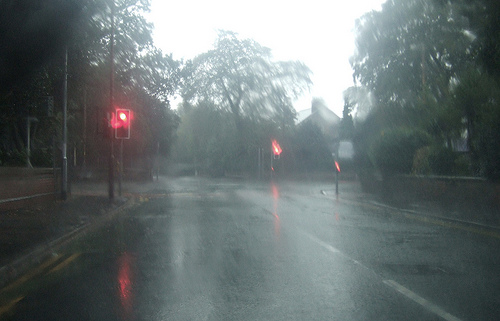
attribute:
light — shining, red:
[113, 107, 132, 127]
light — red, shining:
[116, 249, 134, 303]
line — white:
[279, 205, 447, 319]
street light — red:
[106, 103, 133, 137]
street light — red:
[268, 133, 285, 161]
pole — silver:
[58, 35, 77, 194]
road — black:
[8, 165, 497, 317]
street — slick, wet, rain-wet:
[3, 176, 497, 316]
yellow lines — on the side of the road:
[0, 239, 85, 311]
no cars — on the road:
[0, 159, 470, 319]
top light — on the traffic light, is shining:
[109, 106, 134, 129]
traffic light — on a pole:
[107, 96, 133, 202]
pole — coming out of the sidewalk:
[57, 50, 73, 203]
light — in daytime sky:
[156, 0, 373, 40]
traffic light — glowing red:
[108, 101, 135, 134]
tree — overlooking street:
[176, 30, 300, 180]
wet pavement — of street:
[103, 182, 450, 318]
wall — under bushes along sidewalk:
[381, 170, 477, 213]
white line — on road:
[331, 241, 428, 318]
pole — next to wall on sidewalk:
[55, 37, 75, 198]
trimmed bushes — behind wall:
[367, 124, 483, 176]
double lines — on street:
[2, 253, 76, 319]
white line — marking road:
[321, 239, 424, 311]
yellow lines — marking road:
[1, 241, 75, 319]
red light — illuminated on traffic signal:
[110, 103, 132, 133]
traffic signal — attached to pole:
[108, 106, 136, 133]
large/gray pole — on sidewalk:
[56, 40, 70, 204]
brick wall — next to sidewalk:
[3, 165, 64, 197]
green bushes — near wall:
[369, 125, 453, 175]